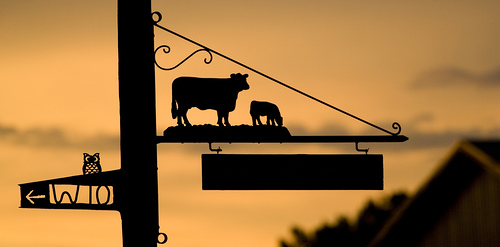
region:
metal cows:
[154, 59, 288, 150]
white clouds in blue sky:
[357, 12, 382, 43]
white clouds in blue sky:
[385, 78, 417, 113]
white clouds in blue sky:
[418, 38, 483, 72]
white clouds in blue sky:
[40, 32, 62, 56]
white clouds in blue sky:
[27, 63, 49, 101]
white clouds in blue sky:
[337, 25, 401, 70]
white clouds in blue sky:
[194, 198, 238, 228]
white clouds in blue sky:
[382, 48, 462, 86]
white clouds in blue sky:
[368, 11, 489, 78]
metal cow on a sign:
[244, 94, 292, 131]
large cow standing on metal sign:
[162, 65, 248, 141]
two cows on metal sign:
[155, 69, 292, 153]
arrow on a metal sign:
[17, 182, 51, 213]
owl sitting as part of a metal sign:
[71, 145, 110, 177]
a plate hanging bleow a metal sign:
[179, 138, 412, 198]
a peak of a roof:
[433, 126, 489, 180]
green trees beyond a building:
[303, 210, 372, 238]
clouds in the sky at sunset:
[404, 59, 493, 124]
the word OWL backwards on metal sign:
[34, 177, 123, 214]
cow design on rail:
[159, 69, 252, 123]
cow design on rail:
[247, 97, 289, 125]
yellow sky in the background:
[13, 0, 498, 230]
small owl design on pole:
[74, 145, 107, 176]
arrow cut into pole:
[15, 182, 52, 211]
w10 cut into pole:
[46, 181, 114, 208]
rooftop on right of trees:
[401, 122, 491, 199]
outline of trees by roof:
[289, 182, 420, 244]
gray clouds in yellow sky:
[391, 68, 496, 98]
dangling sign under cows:
[189, 152, 388, 192]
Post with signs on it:
[115, 2, 160, 246]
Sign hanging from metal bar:
[198, 145, 385, 189]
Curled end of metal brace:
[390, 120, 402, 132]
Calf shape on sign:
[247, 99, 287, 127]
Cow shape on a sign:
[171, 69, 248, 126]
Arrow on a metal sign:
[22, 184, 48, 205]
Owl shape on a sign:
[80, 152, 107, 179]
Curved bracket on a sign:
[150, 42, 215, 68]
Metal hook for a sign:
[350, 138, 371, 155]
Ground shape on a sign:
[165, 119, 292, 139]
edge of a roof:
[391, 195, 401, 204]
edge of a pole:
[152, 163, 160, 173]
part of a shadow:
[228, 227, 234, 239]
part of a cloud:
[379, 24, 391, 37]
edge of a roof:
[422, 214, 427, 225]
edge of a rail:
[306, 140, 313, 142]